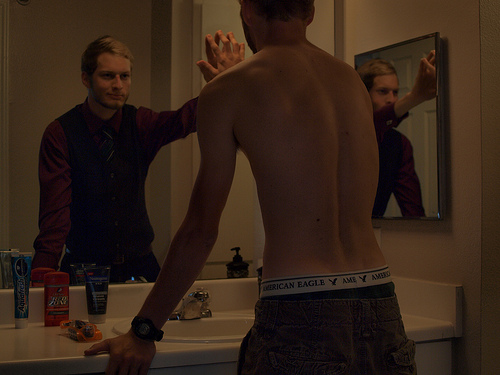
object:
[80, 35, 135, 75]
hair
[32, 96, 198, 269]
shirt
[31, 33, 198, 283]
man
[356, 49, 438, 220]
man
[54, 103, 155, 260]
vest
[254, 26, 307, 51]
neck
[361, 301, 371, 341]
belt loop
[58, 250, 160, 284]
pants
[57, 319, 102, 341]
razor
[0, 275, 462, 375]
counter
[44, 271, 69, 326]
container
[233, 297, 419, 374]
pants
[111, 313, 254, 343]
sink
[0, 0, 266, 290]
mirror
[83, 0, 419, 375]
man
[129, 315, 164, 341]
watch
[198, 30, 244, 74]
hands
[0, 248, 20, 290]
tube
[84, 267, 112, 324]
container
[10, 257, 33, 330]
container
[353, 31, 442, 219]
mirror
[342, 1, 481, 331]
wall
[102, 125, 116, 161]
tie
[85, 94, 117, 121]
man's neck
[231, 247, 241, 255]
pump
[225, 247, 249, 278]
bottle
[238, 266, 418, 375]
clothing